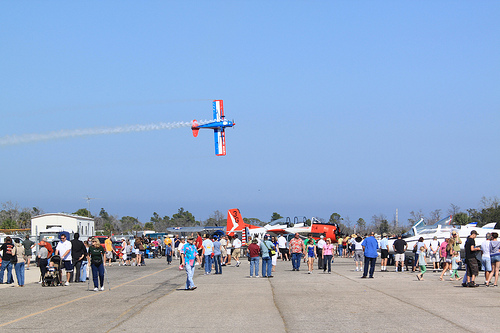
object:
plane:
[191, 100, 235, 156]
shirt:
[181, 242, 199, 266]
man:
[55, 234, 73, 286]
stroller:
[41, 255, 64, 287]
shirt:
[55, 240, 72, 261]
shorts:
[58, 259, 74, 273]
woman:
[87, 238, 106, 292]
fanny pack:
[90, 260, 103, 267]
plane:
[226, 208, 340, 243]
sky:
[1, 1, 499, 155]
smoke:
[0, 119, 195, 144]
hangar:
[29, 212, 96, 242]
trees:
[91, 209, 222, 231]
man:
[181, 236, 201, 291]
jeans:
[184, 264, 197, 290]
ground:
[1, 286, 498, 332]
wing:
[212, 100, 225, 122]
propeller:
[231, 118, 236, 130]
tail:
[191, 119, 200, 138]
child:
[46, 262, 57, 278]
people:
[11, 238, 25, 287]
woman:
[304, 240, 318, 274]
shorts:
[308, 255, 316, 258]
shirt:
[308, 245, 314, 257]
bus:
[37, 227, 74, 249]